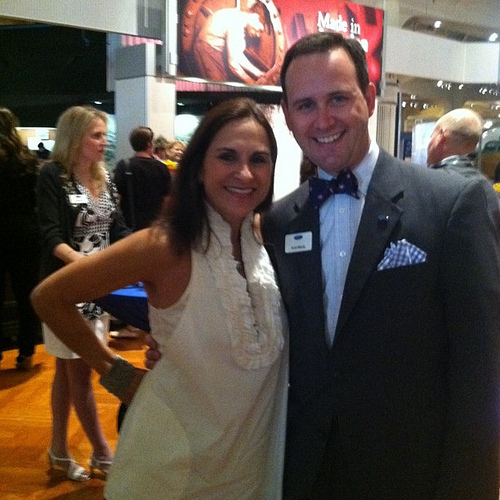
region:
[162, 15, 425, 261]
A smiling man and woman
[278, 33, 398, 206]
A man wearing a bow tie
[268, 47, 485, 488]
A man wearing a suit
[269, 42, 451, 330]
A man wearing a blue shirt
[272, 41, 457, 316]
A man wearing a name tag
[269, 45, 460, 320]
A man wearing a pocket square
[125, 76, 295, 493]
A woman wearing a white top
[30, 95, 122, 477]
A woman wearing a black and white dress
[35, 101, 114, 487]
A woman wearing white sandles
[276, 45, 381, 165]
The head of a man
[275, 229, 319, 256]
Small white name tag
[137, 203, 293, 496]
Long white blouse with ruffled collar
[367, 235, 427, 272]
Blue and white checkered handkerchief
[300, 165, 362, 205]
Dark blue bow tie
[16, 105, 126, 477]
Blonde woman wearing black and white dress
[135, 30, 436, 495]
Man and woman posing for a photo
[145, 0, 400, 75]
Red sign with a figure in front of a wheel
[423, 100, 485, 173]
Back of a man's head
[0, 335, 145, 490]
Wood paneled floor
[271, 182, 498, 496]
Gray suit jacket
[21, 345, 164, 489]
floor is brown hardwood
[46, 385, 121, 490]
floor is brown hardwood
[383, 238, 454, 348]
Square handkerchief in lapelle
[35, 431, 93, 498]
White strappy high heel shoes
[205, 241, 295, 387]
Ruffled front of cocktail dress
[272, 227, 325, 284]
White name tag with black writing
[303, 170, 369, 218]
Blue and spotted bowtie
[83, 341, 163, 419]
Thick bracelet on woman's hand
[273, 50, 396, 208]
Man with a smiling face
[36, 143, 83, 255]
Sleeve of black cardigan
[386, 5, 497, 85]
Second level of area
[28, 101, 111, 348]
Blonde woman wearing black and white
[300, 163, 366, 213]
a blue bow tie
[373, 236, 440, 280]
a blue gingham pocket square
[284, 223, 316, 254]
a white and blue name tag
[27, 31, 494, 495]
a couple at an event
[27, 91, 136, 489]
a blond woman in a black and white outfit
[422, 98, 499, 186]
a bald man in a grey suit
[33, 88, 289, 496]
a woman in a white ruffled dress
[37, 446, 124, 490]
high heeled shoes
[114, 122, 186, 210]
three people talking in the distance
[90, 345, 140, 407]
the woman's bracelet